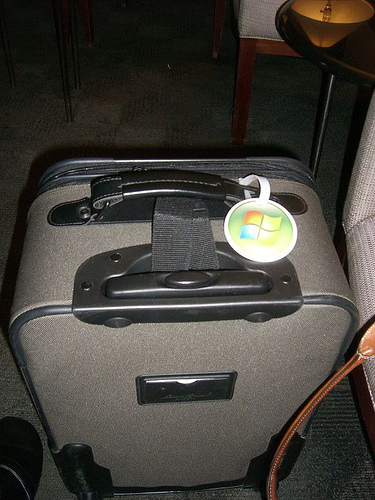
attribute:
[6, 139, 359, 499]
luggage — grey, black, rolling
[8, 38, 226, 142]
carpet — gray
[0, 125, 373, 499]
suitcase — gray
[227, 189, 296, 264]
tag — microsoft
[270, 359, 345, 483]
strap — brown, leather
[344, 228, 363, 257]
cloth — white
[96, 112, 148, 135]
carpet — dark, green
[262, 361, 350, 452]
strap — brown, leather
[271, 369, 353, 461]
strap — brown, leather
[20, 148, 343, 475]
suitcase — grey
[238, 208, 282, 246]
logo — blue, red, white, yellow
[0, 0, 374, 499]
carpet — grey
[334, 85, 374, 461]
chair — light, colored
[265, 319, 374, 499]
purse handle — leather